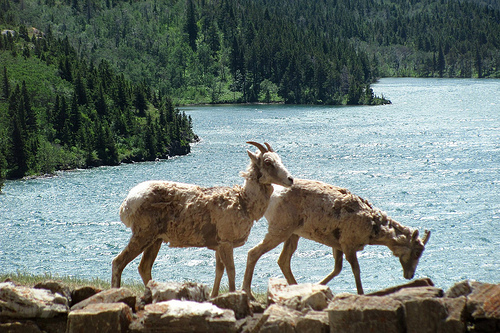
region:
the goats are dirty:
[108, 133, 442, 303]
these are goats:
[105, 135, 439, 303]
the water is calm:
[1, 72, 498, 297]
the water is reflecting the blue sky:
[0, 70, 499, 296]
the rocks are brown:
[1, 271, 498, 331]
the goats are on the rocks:
[113, 130, 441, 303]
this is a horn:
[243, 137, 266, 157]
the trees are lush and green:
[0, 0, 499, 191]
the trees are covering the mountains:
[0, 0, 496, 194]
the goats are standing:
[101, 134, 436, 306]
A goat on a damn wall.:
[99, 112, 296, 292]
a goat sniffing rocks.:
[233, 148, 445, 305]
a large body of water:
[0, 80, 499, 297]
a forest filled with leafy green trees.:
[0, 0, 496, 190]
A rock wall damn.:
[0, 272, 498, 329]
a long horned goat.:
[230, 125, 305, 199]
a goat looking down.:
[345, 222, 452, 299]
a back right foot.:
[90, 242, 144, 293]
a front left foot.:
[352, 255, 369, 297]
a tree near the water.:
[186, 115, 195, 158]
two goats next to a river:
[100, 130, 440, 290]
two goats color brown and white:
[97, 121, 445, 299]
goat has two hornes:
[244, 132, 278, 170]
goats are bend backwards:
[237, 128, 282, 163]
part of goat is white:
[108, 169, 159, 229]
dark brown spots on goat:
[324, 189, 371, 226]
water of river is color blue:
[4, 71, 498, 288]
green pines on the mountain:
[8, 5, 492, 149]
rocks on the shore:
[2, 281, 497, 332]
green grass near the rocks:
[10, 256, 265, 298]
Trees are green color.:
[15, 46, 137, 133]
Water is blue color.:
[300, 110, 475, 180]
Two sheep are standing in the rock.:
[100, 140, 435, 295]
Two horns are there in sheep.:
[245, 130, 275, 155]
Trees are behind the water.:
[20, 50, 285, 195]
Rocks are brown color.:
[18, 277, 284, 330]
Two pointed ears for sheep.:
[242, 143, 277, 163]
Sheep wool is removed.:
[131, 178, 254, 254]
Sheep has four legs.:
[248, 233, 375, 301]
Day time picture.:
[38, 36, 470, 319]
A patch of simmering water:
[325, 113, 498, 174]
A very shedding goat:
[111, 136, 297, 294]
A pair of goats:
[109, 123, 432, 301]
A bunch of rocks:
[0, 273, 499, 331]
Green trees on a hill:
[0, 25, 210, 175]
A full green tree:
[89, 112, 121, 164]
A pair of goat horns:
[246, 136, 273, 156]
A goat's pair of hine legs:
[100, 205, 169, 290]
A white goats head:
[243, 139, 299, 187]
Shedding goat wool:
[136, 183, 240, 247]